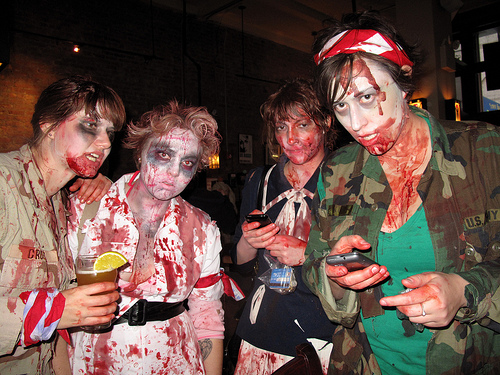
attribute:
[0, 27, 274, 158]
wall — brown 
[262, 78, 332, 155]
hair — brown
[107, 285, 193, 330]
belt — black 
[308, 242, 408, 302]
cell phone — gray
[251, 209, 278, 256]
cell phone — black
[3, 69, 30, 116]
wall — clean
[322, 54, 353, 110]
hair — dark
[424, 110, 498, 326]
shirt — Camo 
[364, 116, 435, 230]
red stain — red 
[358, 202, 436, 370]
green cloth — green 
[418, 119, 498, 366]
green cloth — green 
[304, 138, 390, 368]
green cloth — green 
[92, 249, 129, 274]
slice — orange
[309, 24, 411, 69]
band — red, white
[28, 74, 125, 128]
hair — brown 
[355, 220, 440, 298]
green shirt — green 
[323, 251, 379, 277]
phone — mobile 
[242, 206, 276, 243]
phone — black 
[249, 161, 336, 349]
shirt — black 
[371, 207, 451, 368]
shirt — green 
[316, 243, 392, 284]
phone — grey 